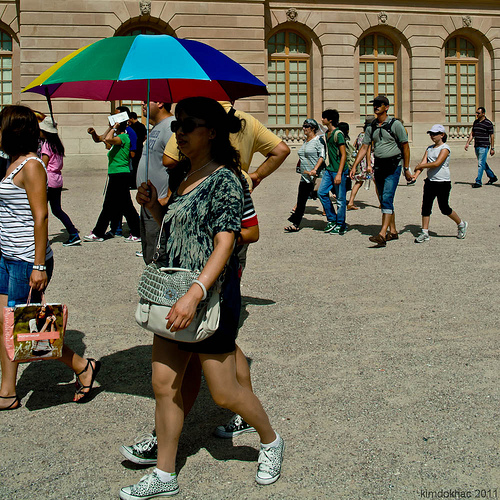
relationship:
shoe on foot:
[120, 428, 165, 467] [116, 427, 160, 466]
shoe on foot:
[120, 432, 171, 470] [118, 430, 159, 467]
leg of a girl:
[193, 313, 275, 446] [118, 95, 285, 498]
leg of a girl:
[143, 324, 184, 488] [118, 95, 285, 498]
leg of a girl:
[149, 329, 194, 470] [118, 95, 285, 498]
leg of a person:
[416, 177, 438, 233] [416, 120, 468, 245]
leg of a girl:
[416, 182, 438, 232] [409, 121, 468, 245]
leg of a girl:
[193, 313, 296, 485] [118, 95, 285, 498]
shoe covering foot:
[252, 433, 285, 484] [255, 433, 284, 481]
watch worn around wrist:
[30, 263, 48, 272] [32, 258, 46, 271]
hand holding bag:
[26, 265, 46, 291] [0, 282, 69, 364]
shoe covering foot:
[367, 232, 387, 246] [368, 232, 388, 246]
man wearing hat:
[312, 101, 358, 234] [370, 95, 398, 106]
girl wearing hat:
[409, 119, 474, 248] [427, 114, 455, 141]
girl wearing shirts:
[134, 151, 276, 473] [231, 163, 262, 310]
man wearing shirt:
[349, 84, 442, 258] [364, 114, 406, 162]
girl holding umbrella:
[118, 95, 285, 498] [17, 11, 277, 124]